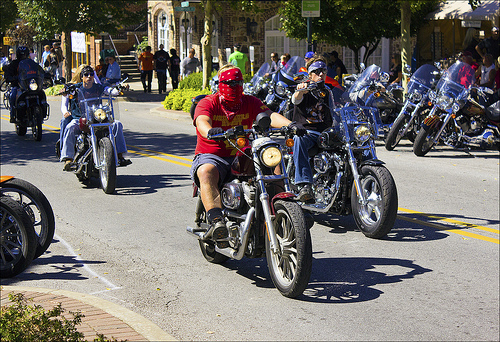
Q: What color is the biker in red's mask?
A: Red.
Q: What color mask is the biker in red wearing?
A: Red.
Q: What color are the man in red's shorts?
A: Blue.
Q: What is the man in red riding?
A: Motorcycle.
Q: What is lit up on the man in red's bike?
A: Head light.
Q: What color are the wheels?
A: Black.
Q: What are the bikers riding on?
A: Street.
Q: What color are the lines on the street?
A: Yellow.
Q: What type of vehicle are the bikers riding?
A: Motorcycles.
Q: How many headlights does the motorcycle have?
A: One.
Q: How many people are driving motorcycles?
A: Four.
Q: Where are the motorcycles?
A: On the pavement.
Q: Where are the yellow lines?
A: Middle of street.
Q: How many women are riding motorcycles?
A: Zero.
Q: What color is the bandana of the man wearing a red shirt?
A: Red.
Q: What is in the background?
A: Buildings.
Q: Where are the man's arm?
A: Holding handlebars.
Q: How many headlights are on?
A: Four.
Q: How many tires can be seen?
A: Ten.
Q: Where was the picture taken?
A: On a street.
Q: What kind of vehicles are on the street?
A: Motorcycles.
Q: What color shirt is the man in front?
A: Red.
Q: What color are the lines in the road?
A: Yellow.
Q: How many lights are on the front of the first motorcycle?
A: 1.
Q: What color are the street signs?
A: Green.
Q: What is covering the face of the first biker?
A: Bandana.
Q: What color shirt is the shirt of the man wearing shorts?
A: Red.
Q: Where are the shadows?
A: On the ground.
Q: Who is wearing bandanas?
A: The bikers.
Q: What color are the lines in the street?
A: Yellow.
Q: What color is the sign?
A: Green and white.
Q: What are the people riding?
A: A motorcycle.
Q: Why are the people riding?
A: They enjoy it.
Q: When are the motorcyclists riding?
A: During the day.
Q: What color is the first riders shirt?
A: Red.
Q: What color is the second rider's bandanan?
A: Blue.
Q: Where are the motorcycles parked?
A: On the side of the road.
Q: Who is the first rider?
A: The one in red.